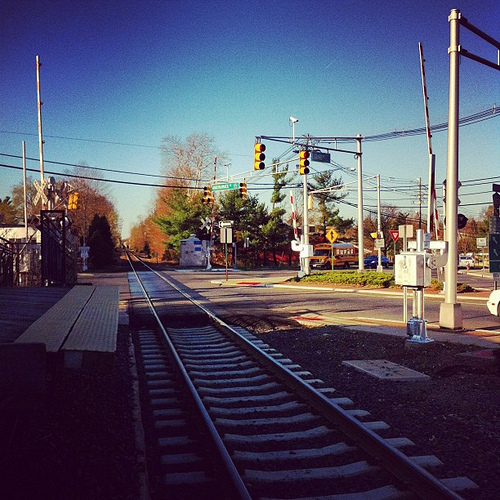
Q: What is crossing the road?
A: Train track.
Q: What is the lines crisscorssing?
A: The road.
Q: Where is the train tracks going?
A: Into the distance.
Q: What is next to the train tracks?
A: Bench.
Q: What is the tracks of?
A: Trains.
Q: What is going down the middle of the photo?
A: Train tracks.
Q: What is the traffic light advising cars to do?
A: Stop.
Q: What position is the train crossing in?
A: Up.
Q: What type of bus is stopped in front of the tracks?
A: School bus.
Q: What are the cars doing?
A: Stopping.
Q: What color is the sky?
A: Blue.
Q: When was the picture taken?
A: Daytime.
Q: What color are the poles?
A: Silver.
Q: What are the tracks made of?
A: Metal.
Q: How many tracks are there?
A: Two.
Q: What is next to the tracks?
A: Gravel.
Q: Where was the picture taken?
A: In the city by a railroad track.